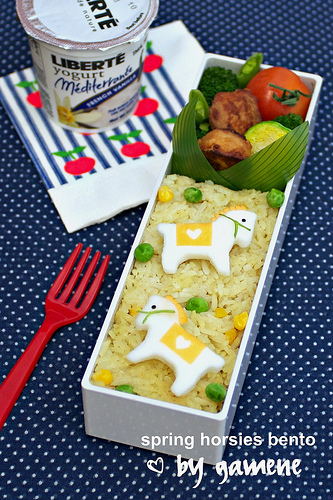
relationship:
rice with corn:
[168, 256, 219, 281] [152, 178, 210, 237]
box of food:
[80, 52, 321, 467] [166, 132, 254, 354]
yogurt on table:
[11, 1, 128, 80] [288, 232, 325, 290]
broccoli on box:
[203, 70, 257, 100] [80, 52, 321, 467]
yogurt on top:
[11, 1, 128, 80] [31, 24, 112, 57]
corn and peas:
[152, 178, 210, 237] [108, 242, 207, 325]